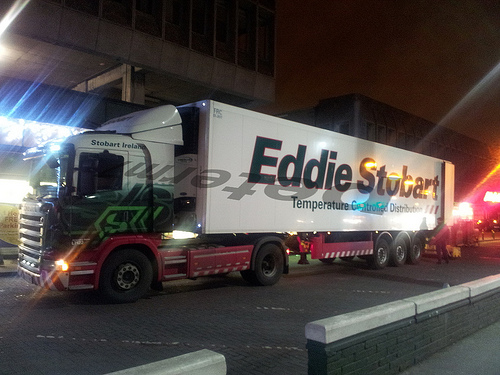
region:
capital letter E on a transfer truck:
[238, 133, 299, 198]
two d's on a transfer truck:
[268, 138, 338, 200]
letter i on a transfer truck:
[310, 146, 357, 191]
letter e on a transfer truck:
[331, 160, 358, 193]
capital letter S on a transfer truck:
[352, 157, 378, 197]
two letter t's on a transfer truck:
[372, 160, 438, 201]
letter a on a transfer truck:
[412, 175, 432, 201]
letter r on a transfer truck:
[411, 166, 443, 208]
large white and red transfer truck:
[27, 126, 464, 301]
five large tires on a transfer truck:
[44, 220, 451, 303]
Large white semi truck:
[17, 66, 463, 301]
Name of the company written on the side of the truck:
[240, 122, 457, 224]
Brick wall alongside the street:
[295, 264, 449, 373]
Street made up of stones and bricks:
[117, 300, 284, 348]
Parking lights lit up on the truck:
[30, 248, 97, 293]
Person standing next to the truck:
[424, 204, 456, 268]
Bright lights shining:
[450, 187, 499, 238]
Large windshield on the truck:
[17, 139, 77, 206]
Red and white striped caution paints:
[307, 242, 379, 262]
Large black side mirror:
[79, 150, 121, 208]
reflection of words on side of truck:
[164, 154, 345, 220]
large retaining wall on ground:
[289, 297, 464, 344]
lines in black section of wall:
[343, 348, 453, 374]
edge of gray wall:
[291, 310, 341, 346]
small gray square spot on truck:
[195, 95, 247, 132]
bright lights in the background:
[457, 165, 498, 245]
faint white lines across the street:
[61, 312, 174, 351]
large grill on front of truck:
[3, 204, 70, 266]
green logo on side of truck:
[75, 190, 194, 242]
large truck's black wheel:
[99, 233, 171, 322]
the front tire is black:
[98, 241, 157, 312]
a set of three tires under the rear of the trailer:
[373, 222, 428, 268]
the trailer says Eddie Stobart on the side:
[238, 132, 443, 199]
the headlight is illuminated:
[54, 255, 74, 274]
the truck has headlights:
[49, 256, 71, 276]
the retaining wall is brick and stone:
[306, 272, 499, 374]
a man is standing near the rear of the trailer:
[428, 213, 457, 264]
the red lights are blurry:
[482, 183, 499, 201]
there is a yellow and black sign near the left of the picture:
[1, 203, 21, 249]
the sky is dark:
[251, 0, 498, 146]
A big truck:
[0, 127, 472, 272]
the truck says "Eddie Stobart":
[215, 141, 453, 198]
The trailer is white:
[159, 132, 457, 231]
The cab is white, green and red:
[20, 97, 176, 357]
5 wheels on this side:
[61, 226, 440, 306]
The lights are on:
[45, 243, 86, 280]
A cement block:
[282, 276, 485, 364]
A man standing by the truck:
[422, 215, 452, 269]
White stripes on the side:
[300, 242, 372, 274]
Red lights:
[450, 165, 498, 243]